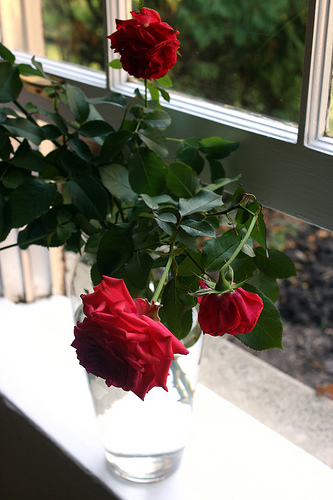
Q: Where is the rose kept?
A: In the vase.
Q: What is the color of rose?
A: Red.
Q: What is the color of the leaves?
A: Green.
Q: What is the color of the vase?
A: White.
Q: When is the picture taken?
A: Daytime.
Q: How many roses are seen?
A: 3.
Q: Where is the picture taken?
A: A window sill.